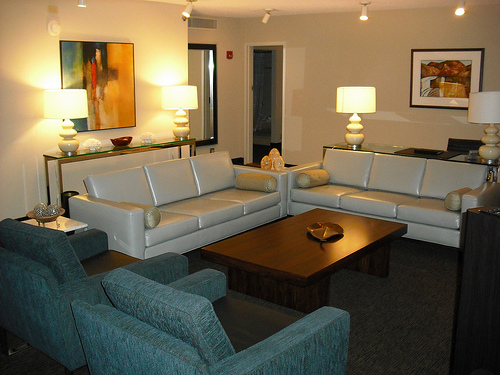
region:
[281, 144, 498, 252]
White three seated couch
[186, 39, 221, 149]
Black trimmed hung mirror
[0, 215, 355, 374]
Two blue chairs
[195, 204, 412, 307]
Tray on wooden coffee table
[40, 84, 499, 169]
Four white lamps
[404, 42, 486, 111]
Black framed art piece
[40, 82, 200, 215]
Two lamps on a table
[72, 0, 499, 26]
Five lights on ceiling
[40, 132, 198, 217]
Red bowl on table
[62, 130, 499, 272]
refined leather sofas, contemporary styling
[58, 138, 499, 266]
sofas are beige/griege, they -might- be vinyl but likely arent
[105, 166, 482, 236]
four oblong pillows in almost, but not precisely, the same colour as sofas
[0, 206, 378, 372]
two blue on blue possibly jacquard chairs with either black seat pillows or missing seat pillows [hard to tell]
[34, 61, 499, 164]
four lamps w/ bases contrived of multiple rounded edge bowl-like components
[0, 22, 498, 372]
all furniture is vintage/atomic 'reminiscent'; it's not cheap, it's expensive, but it's retro & not the real thing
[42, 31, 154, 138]
painting is the same type thing, semi-expensive original but a copied style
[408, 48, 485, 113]
this one is too far away for me to parse well, but from here it looks like a diego rivera or siqueiros rip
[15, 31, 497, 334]
a living room area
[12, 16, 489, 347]
the living room is white and blue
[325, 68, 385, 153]
the lamp is on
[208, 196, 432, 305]
a wooden table in the middle of the room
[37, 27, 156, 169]
a picture on the wall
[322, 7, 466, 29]
lights on the ceiling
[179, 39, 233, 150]
mirror on the wall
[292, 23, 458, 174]
white walls in the living room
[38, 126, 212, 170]
a stand behind the couch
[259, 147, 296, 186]
a decoration on the end table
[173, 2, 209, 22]
glowing light in room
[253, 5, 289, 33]
glowing light in room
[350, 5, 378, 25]
glowing light in room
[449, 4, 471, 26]
glowing light in room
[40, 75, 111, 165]
glowing light in room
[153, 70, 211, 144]
glowing light in room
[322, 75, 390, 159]
glowing light in room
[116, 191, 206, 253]
couch cushion in room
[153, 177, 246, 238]
couch cushion in room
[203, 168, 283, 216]
couch cushion in room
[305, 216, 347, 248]
plate on the table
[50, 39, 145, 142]
picture on the wall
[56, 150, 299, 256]
leather sofa in the livingroom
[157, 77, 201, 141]
lamp on the table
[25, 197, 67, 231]
fixture on the table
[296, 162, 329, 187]
pillow on the table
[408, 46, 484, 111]
Picture in ta frame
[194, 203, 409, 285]
coffee table in the livingroom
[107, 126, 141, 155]
bowl on a table